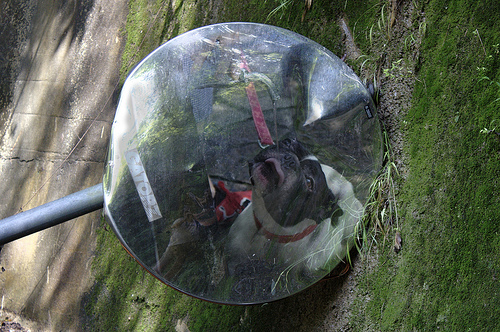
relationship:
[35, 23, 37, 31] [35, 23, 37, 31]
exist dont exist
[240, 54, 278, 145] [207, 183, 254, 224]
stripe on shoe